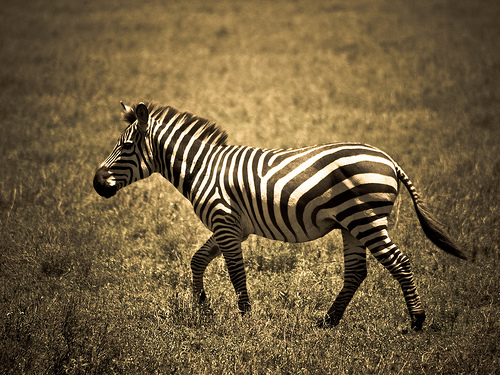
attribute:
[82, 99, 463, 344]
zebra — striped, stripedy